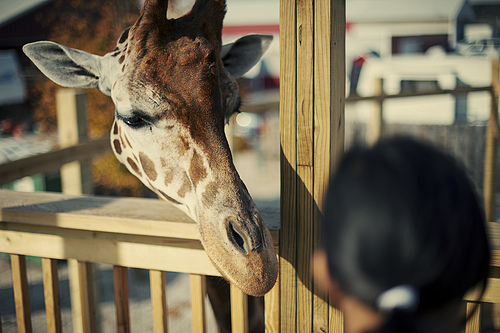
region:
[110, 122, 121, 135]
brown spot on giraffe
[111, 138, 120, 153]
brown spot on giraffe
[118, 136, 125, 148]
brown spot on giraffe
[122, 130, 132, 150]
brown spot on giraffe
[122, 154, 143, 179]
brown spot on giraffe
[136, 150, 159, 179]
brown spot on giraffe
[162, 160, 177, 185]
brown spot on giraffe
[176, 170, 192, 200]
brown spot on giraffe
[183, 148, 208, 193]
brown spot on giraffe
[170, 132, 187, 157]
brown spot on giraffe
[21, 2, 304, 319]
Head of a giraffe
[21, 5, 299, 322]
Head of a giraffe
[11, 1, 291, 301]
Head of a giraffe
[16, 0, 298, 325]
Head of a giraffe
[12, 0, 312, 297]
Head of a giraffe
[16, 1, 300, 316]
Head of a giraffe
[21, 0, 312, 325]
Head of a giraffe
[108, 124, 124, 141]
brown spot on giraffe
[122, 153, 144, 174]
brown spot on giraffe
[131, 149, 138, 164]
brown spot on giraffe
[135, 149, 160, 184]
brown spot on giraffe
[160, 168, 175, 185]
brown spot on giraffe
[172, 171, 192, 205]
brown spot on giraffe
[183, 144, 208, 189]
brown spot on giraffe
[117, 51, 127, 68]
brown spot on giraffe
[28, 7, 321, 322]
this is a giraffe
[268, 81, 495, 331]
this is a person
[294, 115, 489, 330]
person has black hair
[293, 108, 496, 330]
person has a ponytail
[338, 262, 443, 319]
ponytail holder is white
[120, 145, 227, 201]
brown spots on giraffe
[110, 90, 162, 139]
dark eye of giraffe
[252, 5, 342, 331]
this is a wooden post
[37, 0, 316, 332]
giraffe sticking head over wood railing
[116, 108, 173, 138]
eye of the giraffe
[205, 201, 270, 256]
nose of the giraffe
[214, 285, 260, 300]
mouth of the giraffe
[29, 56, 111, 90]
ear of the giraffe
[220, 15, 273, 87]
ear of the giraffe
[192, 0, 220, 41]
horn of the giraffe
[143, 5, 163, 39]
horn of the giraffe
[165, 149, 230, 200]
spots on the giraffe